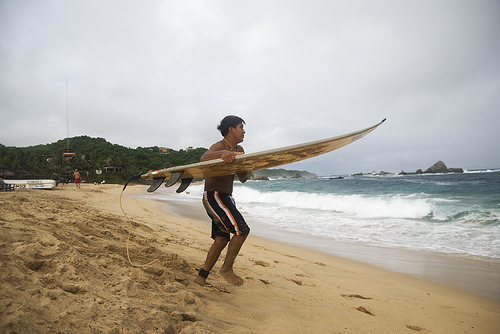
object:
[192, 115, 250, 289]
man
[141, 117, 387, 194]
surfboard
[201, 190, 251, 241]
shorts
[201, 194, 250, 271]
leg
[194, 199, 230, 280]
leg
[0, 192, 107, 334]
sand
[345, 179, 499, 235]
water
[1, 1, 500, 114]
sky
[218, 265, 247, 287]
foot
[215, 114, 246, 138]
hair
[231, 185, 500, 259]
waves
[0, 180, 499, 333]
beach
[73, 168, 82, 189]
person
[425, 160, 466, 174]
rocks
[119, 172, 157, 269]
leash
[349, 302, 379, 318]
footprints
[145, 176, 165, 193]
fin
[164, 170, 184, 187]
fin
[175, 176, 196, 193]
fin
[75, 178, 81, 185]
shorts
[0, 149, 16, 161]
trees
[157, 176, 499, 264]
shore